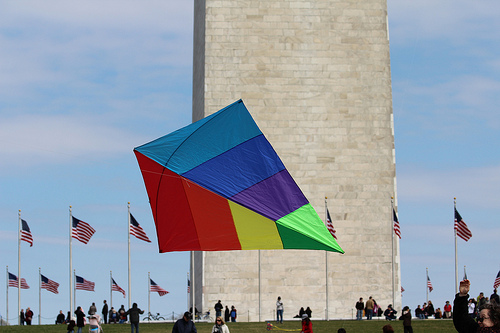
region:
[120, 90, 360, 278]
a rainbow colored kite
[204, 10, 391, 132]
the stone exterior of a monument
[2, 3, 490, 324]
people standing beside the Washington monument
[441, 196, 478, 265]
American flag on a pole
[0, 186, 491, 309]
many American flags on poles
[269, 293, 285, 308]
a person wearing a white shirt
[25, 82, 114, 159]
clouds in the sky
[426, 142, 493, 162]
a patch of blue sky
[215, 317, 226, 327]
a person wearing sunglasses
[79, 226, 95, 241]
red and white stripes on a flag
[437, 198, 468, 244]
flag on a pole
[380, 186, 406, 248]
flag on a pole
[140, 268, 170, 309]
flag on a pole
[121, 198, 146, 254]
flag on a pole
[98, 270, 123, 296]
flag on a pole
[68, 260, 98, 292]
flag on a pole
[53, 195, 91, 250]
flag on a pole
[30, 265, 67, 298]
flag on a pole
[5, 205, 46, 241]
flag on a pole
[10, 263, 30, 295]
flag on a pole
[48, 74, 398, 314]
this is a flag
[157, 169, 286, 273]
the flag is large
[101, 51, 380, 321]
the flag is a diamond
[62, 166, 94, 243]
this is a flag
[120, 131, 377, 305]
the kite is colorful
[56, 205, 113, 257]
this is the american flag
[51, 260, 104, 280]
this is a pole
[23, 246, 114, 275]
this is a flagpole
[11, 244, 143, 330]
the pole is white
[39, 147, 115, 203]
this is a cloud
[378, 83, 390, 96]
part of a building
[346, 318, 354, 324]
part of a grass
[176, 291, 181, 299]
edge of a flag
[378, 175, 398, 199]
part of a tower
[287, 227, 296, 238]
edge of a kite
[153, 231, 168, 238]
part of a rope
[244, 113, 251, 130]
edge of a kite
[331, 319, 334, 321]
part of a grass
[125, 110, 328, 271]
colorful kite in air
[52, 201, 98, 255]
red white and blue flag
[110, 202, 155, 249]
red white and blue flag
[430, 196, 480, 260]
red white and blue flag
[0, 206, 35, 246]
red white and blue flag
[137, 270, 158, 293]
red white and blue flag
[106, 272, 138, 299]
red white and blue flag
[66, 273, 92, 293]
red white and blue flag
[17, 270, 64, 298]
red white and blue flag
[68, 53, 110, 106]
white clouds in blue sky